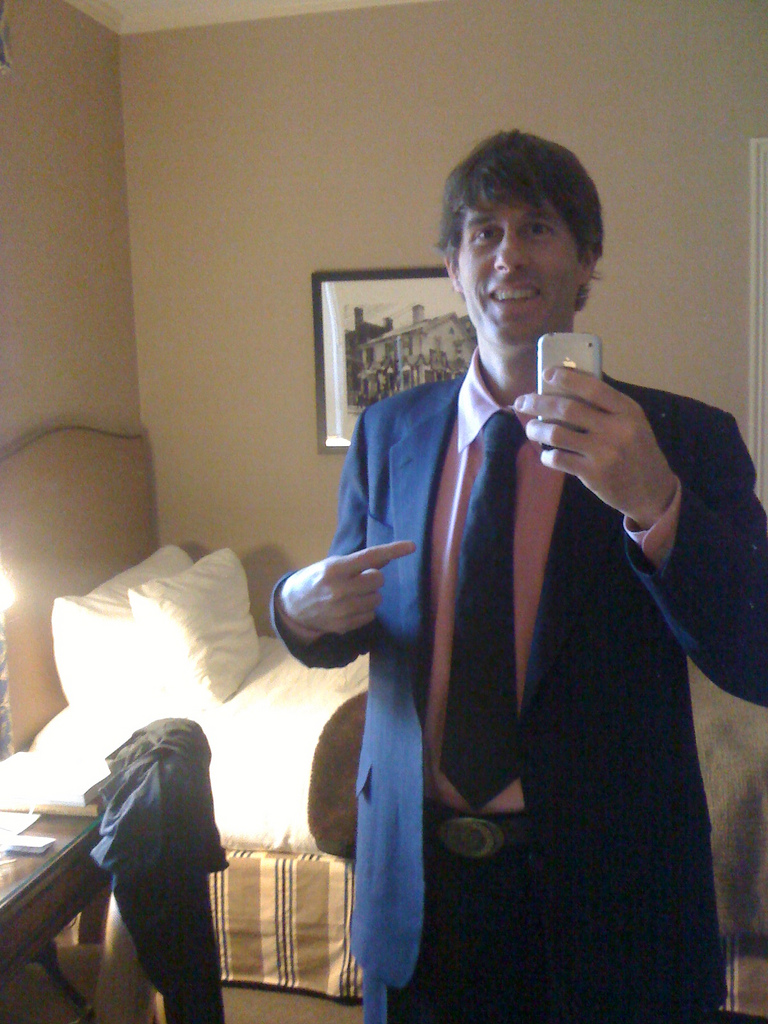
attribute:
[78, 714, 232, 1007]
jacket — BLACK